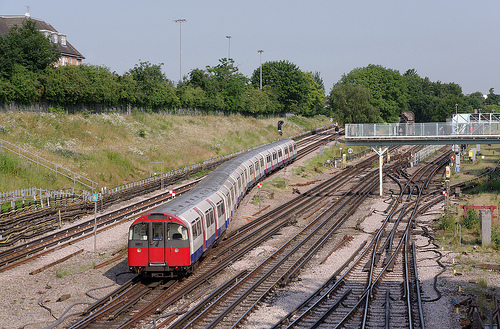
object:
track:
[69, 276, 210, 329]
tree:
[249, 58, 327, 116]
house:
[0, 3, 87, 70]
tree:
[0, 14, 63, 71]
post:
[173, 17, 187, 83]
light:
[174, 19, 188, 24]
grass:
[272, 177, 287, 190]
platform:
[341, 121, 500, 198]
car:
[125, 202, 207, 283]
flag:
[256, 182, 262, 188]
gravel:
[246, 195, 395, 328]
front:
[126, 211, 191, 279]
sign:
[148, 212, 168, 220]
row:
[79, 192, 428, 213]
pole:
[58, 209, 62, 229]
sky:
[1, 0, 499, 95]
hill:
[0, 111, 333, 213]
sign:
[460, 203, 500, 219]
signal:
[277, 120, 285, 135]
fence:
[0, 98, 306, 118]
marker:
[465, 150, 473, 163]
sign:
[92, 193, 98, 202]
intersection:
[377, 207, 419, 235]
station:
[0, 106, 500, 327]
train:
[124, 134, 300, 281]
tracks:
[202, 308, 232, 329]